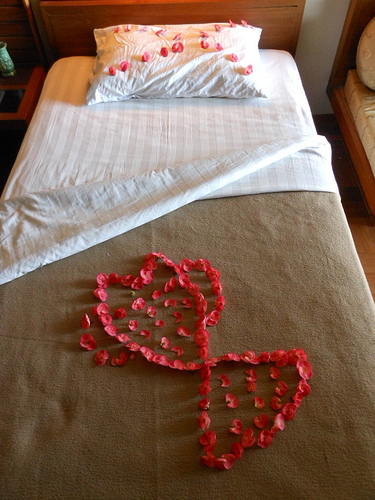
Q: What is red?
A: Flower petals.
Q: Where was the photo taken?
A: In a bedroom.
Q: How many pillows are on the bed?
A: One.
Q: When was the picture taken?
A: Daytime.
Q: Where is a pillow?
A: On the bed.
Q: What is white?
A: Bed sheets.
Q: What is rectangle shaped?
A: A pillow.